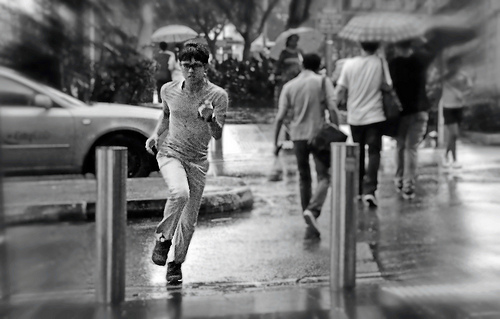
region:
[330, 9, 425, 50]
checkered design umbrella visible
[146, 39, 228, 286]
a young man running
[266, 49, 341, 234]
a man walking in street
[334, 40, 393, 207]
a man walking in street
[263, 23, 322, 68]
a person standing under umbrella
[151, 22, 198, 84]
a person standing under umbrella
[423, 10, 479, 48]
an open umbrella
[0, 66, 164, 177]
a parked car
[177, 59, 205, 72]
a pair of glasses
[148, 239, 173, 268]
black tennis shoes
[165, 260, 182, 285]
a tall tree trunk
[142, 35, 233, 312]
young person runs in the rain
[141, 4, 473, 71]
several people in the background carry open umbrellas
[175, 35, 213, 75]
runner wears bangs+specs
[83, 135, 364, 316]
two round metal poles up front, one @ right has sticker @ top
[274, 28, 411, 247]
two men, the first w/ an open umbrella, carry shoulder bags around right shoulders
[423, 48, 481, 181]
woman, mid-right, wears dark colour shorts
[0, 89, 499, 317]
ground is wet from one end to the other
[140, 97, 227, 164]
runner has one hand in something like a fist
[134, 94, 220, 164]
runner carries, i believe, a mobile telephone in one hand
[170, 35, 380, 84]
all pictured males have short, very dark hair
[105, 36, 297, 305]
a kid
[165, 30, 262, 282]
a kid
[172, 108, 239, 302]
a kid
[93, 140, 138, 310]
A post on the sidewalk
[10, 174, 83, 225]
A curb on the road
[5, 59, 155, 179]
A car on the street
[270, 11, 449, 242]
People walk in the road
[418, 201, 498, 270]
The road is wet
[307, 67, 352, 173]
The man has a bag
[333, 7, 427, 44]
An umbrella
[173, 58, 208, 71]
they wear a pair of glasses.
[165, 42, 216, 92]
They have short hair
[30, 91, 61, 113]
The side view mirror for the car